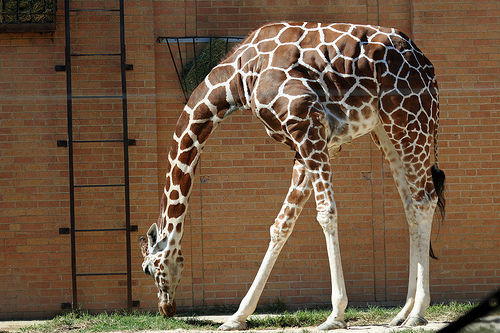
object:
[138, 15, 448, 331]
giraffe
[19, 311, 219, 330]
grass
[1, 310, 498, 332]
ground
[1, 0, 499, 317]
wall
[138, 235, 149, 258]
horns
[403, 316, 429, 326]
hoofs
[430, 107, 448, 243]
tail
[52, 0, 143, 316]
ladder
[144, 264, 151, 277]
eye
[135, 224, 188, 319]
head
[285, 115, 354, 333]
legs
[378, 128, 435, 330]
hind legs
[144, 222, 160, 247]
ear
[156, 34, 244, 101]
feeder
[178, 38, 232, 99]
hay